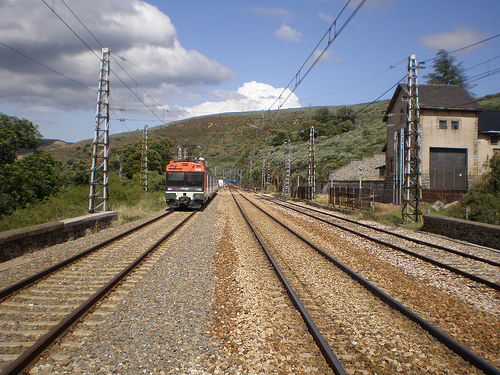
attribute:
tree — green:
[1, 111, 67, 217]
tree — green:
[105, 134, 169, 190]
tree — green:
[300, 101, 338, 139]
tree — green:
[330, 101, 358, 133]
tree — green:
[420, 47, 464, 85]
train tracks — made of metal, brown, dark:
[0, 210, 499, 371]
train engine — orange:
[163, 145, 220, 212]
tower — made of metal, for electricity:
[88, 46, 114, 213]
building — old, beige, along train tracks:
[359, 83, 497, 208]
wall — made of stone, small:
[3, 211, 122, 262]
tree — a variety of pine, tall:
[427, 49, 474, 99]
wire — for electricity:
[0, 4, 478, 137]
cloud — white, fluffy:
[171, 83, 295, 118]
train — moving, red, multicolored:
[163, 145, 219, 212]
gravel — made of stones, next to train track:
[12, 206, 498, 374]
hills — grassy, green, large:
[50, 107, 305, 167]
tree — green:
[0, 115, 54, 215]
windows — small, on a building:
[436, 120, 460, 130]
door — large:
[429, 147, 470, 208]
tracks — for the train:
[4, 210, 213, 347]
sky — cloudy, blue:
[3, 2, 500, 97]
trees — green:
[4, 103, 382, 226]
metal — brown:
[91, 220, 447, 251]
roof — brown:
[382, 83, 484, 122]